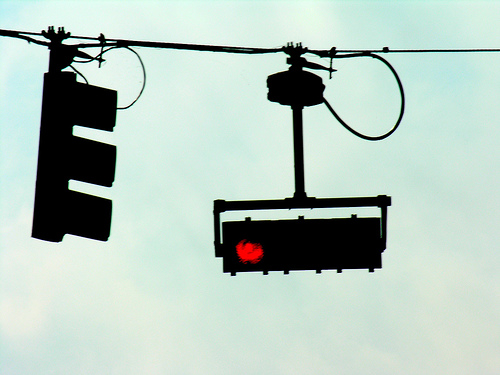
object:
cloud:
[17, 250, 150, 335]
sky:
[0, 0, 500, 371]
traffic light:
[221, 216, 384, 275]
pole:
[291, 104, 309, 198]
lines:
[323, 53, 405, 141]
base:
[212, 196, 392, 214]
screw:
[299, 42, 303, 47]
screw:
[290, 41, 294, 47]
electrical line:
[0, 28, 499, 53]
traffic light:
[32, 72, 120, 242]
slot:
[229, 271, 238, 277]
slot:
[283, 270, 290, 275]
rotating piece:
[267, 71, 326, 108]